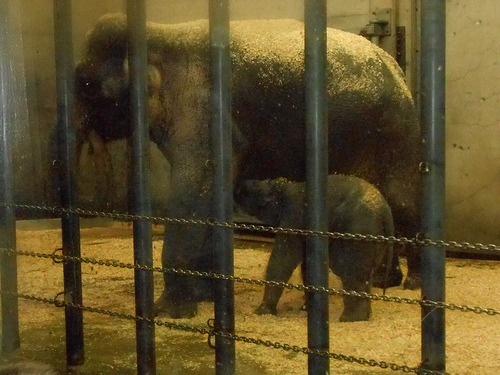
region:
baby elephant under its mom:
[246, 165, 382, 320]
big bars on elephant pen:
[413, 172, 454, 294]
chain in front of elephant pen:
[298, 271, 408, 340]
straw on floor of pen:
[464, 270, 491, 310]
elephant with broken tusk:
[71, 126, 106, 163]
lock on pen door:
[363, 13, 390, 65]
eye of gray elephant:
[78, 65, 95, 99]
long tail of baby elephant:
[381, 214, 390, 289]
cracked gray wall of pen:
[470, 47, 487, 167]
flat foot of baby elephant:
[255, 288, 275, 327]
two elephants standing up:
[39, 15, 453, 342]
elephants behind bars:
[44, 20, 450, 330]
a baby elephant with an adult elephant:
[49, 13, 446, 338]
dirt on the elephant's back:
[172, 13, 423, 105]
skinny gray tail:
[372, 196, 393, 308]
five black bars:
[41, 0, 476, 374]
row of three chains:
[2, 188, 492, 373]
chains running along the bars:
[3, 190, 499, 367]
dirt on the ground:
[9, 213, 498, 374]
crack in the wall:
[448, 60, 487, 91]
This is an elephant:
[231, 163, 393, 335]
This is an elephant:
[49, 7, 438, 324]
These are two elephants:
[40, 13, 461, 335]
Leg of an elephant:
[151, 125, 214, 342]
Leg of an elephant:
[198, 154, 245, 318]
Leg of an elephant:
[250, 221, 300, 320]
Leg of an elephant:
[339, 255, 374, 325]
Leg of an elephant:
[383, 157, 436, 294]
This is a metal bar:
[45, 6, 97, 367]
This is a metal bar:
[124, 11, 176, 372]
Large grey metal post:
[189, 2, 270, 372]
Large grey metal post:
[400, 1, 457, 368]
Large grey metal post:
[285, 3, 360, 368]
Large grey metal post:
[112, 5, 164, 373]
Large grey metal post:
[37, 6, 100, 368]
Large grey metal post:
[7, 7, 32, 362]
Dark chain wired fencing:
[2, 190, 492, 372]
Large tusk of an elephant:
[75, 116, 120, 185]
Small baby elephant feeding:
[232, 174, 354, 291]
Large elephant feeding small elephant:
[47, 15, 432, 346]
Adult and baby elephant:
[42, 6, 439, 335]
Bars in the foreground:
[53, 7, 472, 359]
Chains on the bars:
[3, 190, 490, 365]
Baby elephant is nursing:
[216, 131, 320, 257]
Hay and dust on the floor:
[3, 207, 494, 366]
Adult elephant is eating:
[36, 55, 144, 230]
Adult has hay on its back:
[110, 14, 432, 130]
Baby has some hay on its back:
[332, 165, 397, 227]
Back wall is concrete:
[423, 3, 495, 263]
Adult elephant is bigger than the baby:
[42, 8, 442, 329]